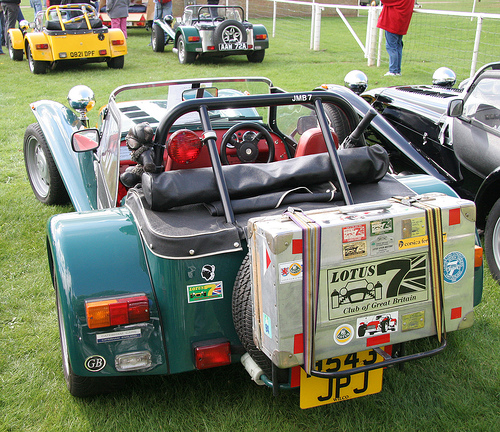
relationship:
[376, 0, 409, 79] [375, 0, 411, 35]
man standing in jacket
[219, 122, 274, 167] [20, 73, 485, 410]
steering wheel on buggy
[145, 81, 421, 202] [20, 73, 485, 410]
roll cage on buggy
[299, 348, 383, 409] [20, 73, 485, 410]
jpj tag on buggy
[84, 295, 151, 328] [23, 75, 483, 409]
light on buggy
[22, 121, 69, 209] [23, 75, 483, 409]
wheel on buggy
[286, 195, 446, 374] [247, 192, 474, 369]
strap on suitcase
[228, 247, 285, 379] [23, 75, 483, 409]
spare tire on buggy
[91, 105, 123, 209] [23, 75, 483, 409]
window on buggy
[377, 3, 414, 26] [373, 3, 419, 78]
jacket on person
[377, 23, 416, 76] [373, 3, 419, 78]
jeans on person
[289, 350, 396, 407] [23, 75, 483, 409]
jpj tag on buggy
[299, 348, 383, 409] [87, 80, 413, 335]
jpj tag on car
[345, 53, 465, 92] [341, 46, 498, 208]
tag on car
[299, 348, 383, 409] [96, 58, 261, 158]
jpj tag on car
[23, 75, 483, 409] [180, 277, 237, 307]
buggy has signal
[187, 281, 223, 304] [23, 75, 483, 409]
signal on buggy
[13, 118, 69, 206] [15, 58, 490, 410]
front tire on car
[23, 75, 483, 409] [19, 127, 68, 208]
buggy has wheel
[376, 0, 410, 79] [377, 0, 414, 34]
man wearing jacket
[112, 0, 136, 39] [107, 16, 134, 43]
person wearing pink pants